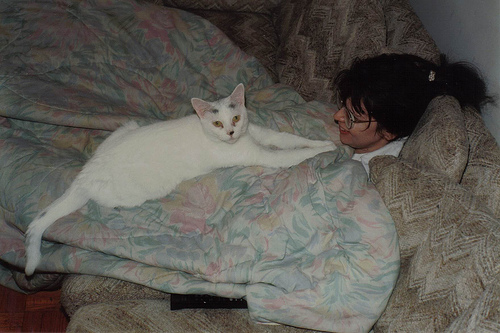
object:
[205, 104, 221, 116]
spot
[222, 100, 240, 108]
spot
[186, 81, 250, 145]
head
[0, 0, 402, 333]
comforter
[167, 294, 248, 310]
remote control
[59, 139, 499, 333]
couch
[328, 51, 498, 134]
hair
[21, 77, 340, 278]
cat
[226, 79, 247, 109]
ear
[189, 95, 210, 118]
ear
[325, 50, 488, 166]
woman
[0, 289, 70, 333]
floors